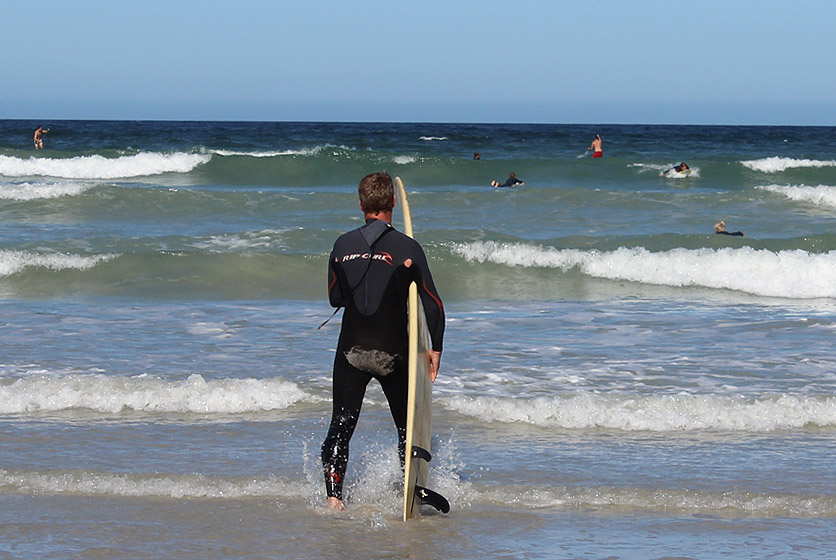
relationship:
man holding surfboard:
[309, 164, 451, 527] [391, 176, 439, 524]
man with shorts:
[588, 134, 603, 158] [589, 148, 608, 160]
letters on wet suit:
[329, 247, 391, 269] [320, 218, 450, 496]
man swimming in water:
[588, 134, 603, 158] [1, 124, 806, 557]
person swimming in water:
[480, 164, 540, 194] [1, 124, 806, 557]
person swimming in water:
[653, 155, 700, 186] [1, 124, 806, 557]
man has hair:
[309, 164, 451, 527] [352, 167, 400, 214]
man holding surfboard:
[309, 164, 451, 527] [388, 171, 448, 523]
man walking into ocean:
[309, 164, 451, 527] [1, 118, 800, 557]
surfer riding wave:
[30, 123, 54, 154] [0, 139, 445, 202]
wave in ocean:
[0, 139, 445, 202] [1, 118, 800, 557]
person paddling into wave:
[489, 172, 525, 188] [1, 139, 809, 202]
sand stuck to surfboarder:
[340, 345, 397, 381] [309, 167, 456, 521]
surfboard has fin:
[396, 173, 432, 519] [411, 443, 436, 464]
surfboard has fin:
[396, 173, 432, 519] [417, 483, 455, 519]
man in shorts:
[581, 127, 609, 158] [589, 147, 611, 157]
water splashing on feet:
[350, 434, 470, 516] [325, 492, 355, 519]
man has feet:
[315, 171, 445, 513] [325, 492, 355, 519]